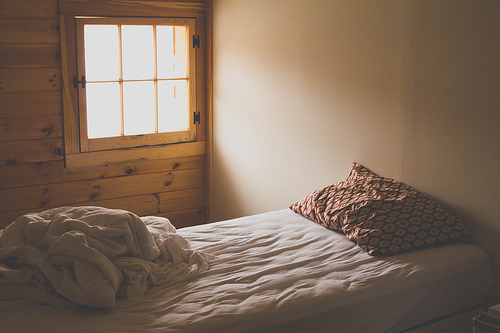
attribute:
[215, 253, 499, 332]
bed — small, unmade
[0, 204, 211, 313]
bedding — crumpled, white, piled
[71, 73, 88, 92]
hinge — black, three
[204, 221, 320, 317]
bed mattress — wrinkled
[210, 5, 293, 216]
wall — light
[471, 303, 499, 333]
edge — cornered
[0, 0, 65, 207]
wood wall — portioned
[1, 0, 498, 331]
bedroom — small, cozy, singular, personal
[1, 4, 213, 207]
walls — wooden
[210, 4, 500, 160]
beige — the wall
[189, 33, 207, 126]
hardware — black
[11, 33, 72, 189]
wall — brown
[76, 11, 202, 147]
window — closed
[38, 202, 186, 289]
blanket — white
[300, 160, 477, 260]
pillow — rectangle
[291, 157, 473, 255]
pillow — printed, patterned, wrinkled, brown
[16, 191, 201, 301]
blanket — rumpled